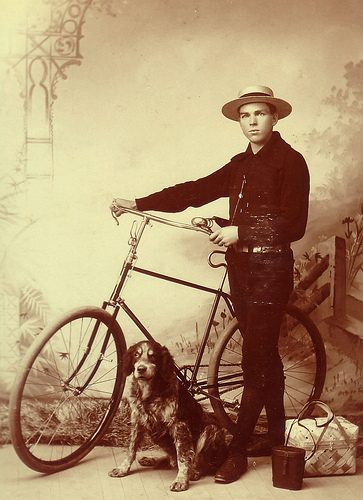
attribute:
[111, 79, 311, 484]
person — wall , hand 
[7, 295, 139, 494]
wheel — round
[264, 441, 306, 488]
patch — small, brown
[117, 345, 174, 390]
dog — head 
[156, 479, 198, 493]
dog — paw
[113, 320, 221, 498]
dog — camera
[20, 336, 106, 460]
tire — spokes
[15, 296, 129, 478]
tire — bike 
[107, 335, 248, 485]
dog — dark, light 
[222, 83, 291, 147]
person — head 